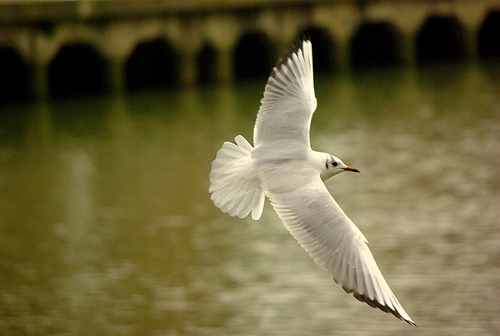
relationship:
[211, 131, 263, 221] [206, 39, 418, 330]
tail of bird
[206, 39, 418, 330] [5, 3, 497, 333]
bird flying in sky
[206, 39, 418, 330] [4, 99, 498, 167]
bird flying in sky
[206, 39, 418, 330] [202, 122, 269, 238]
bird has tail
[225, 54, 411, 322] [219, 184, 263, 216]
bird has white feathers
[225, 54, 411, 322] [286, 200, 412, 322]
bird has a wing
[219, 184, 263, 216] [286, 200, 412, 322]
feathers are on a wing